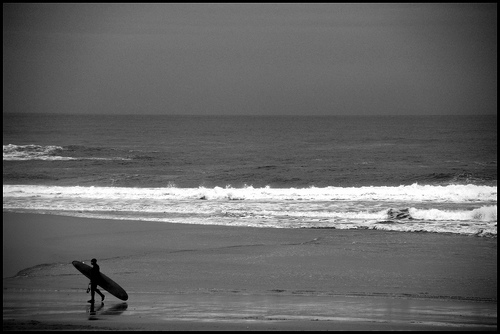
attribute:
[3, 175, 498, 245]
wave — small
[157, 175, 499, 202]
foam — white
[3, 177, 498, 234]
ripples — Small 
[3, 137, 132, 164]
ripples — Small 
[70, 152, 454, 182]
ripples — small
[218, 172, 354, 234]
ripples — small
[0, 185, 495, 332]
beach — wet , sandy 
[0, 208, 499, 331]
beach — black and white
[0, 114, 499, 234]
ripples — small